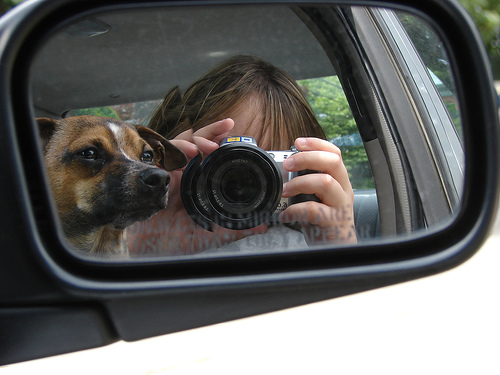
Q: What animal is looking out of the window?
A: A dog.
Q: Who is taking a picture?
A: The person.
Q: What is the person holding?
A: A camera.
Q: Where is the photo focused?
A: In the car's side mirror.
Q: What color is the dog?
A: Brown.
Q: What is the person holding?
A: A camera.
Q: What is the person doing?
A: Taking a picture.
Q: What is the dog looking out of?
A: The window.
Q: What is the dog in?
A: A car.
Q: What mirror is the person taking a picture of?
A: Side view mirror.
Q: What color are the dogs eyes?
A: Black.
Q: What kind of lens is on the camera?
A: Wide angle.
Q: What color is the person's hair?
A: Brown.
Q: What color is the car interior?
A: Grey.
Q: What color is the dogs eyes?
A: Black.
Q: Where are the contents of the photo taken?
A: A car.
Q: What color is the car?
A: Silver.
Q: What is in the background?
A: Trees.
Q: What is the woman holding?
A: A camera.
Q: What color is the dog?
A: Brown and Black.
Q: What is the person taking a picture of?
A: Themselves and dog.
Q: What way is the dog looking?
A: Right.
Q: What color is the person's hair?
A: Brown.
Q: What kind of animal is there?
A: Dog.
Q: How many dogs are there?
A: One.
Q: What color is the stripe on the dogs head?
A: White.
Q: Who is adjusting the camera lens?
A: The girl.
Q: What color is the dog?
A: Brown and black.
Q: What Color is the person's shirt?
A: White.